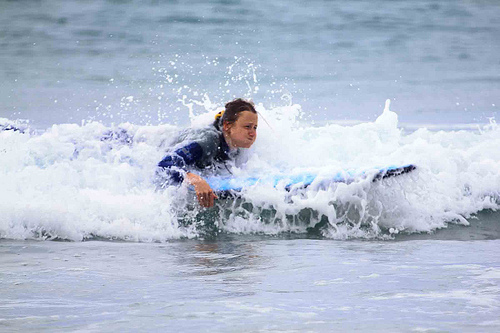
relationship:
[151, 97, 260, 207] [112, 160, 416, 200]
paddling woman on a surfboard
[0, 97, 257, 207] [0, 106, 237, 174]
paddling woman wearing wet suit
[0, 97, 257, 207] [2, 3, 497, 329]
paddling woman in water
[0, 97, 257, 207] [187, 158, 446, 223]
paddling woman riding surfboard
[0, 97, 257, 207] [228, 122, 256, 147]
paddling woman has cheeks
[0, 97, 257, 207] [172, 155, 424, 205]
paddling woman swimming on surfboard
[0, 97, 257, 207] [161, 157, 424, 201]
paddling woman on board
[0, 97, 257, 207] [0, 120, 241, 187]
paddling woman wears wet suit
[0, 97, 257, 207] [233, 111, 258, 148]
paddling woman has face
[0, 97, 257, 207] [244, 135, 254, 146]
paddling woman has mouth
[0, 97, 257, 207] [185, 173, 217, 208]
paddling woman has hand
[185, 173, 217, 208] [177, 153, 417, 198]
hand on surf board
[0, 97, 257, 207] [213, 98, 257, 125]
paddling woman has hair